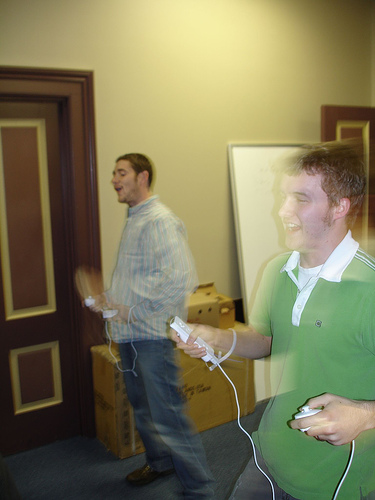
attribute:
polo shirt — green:
[247, 227, 373, 495]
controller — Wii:
[80, 292, 123, 322]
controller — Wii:
[170, 315, 331, 434]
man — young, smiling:
[164, 147, 373, 499]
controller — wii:
[285, 376, 353, 445]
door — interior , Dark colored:
[3, 55, 107, 458]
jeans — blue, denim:
[119, 339, 216, 499]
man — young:
[82, 152, 218, 498]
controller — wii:
[99, 307, 120, 320]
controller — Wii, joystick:
[87, 294, 114, 319]